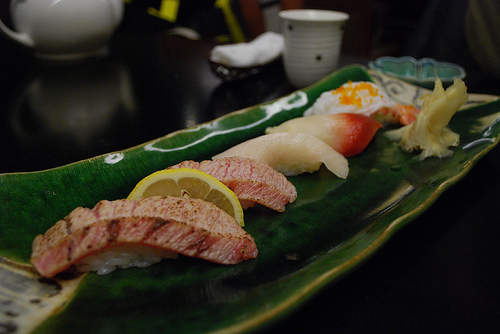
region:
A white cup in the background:
[280, 3, 350, 73]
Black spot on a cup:
[314, 52, 322, 60]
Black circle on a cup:
[315, 53, 323, 62]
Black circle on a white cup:
[315, 53, 323, 60]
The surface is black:
[29, 65, 155, 122]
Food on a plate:
[16, 46, 445, 303]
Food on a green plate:
[21, 75, 458, 307]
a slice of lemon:
[109, 163, 257, 228]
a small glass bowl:
[356, 45, 473, 110]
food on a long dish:
[3, 50, 498, 332]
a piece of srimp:
[7, 187, 304, 284]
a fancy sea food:
[15, 80, 435, 332]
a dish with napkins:
[198, 21, 283, 84]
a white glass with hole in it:
[236, 9, 366, 93]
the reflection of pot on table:
[8, 27, 149, 159]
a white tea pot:
[2, 1, 180, 71]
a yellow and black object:
[146, 2, 251, 37]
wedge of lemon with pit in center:
[125, 166, 243, 229]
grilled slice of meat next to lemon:
[32, 194, 259, 274]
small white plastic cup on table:
[277, 7, 347, 89]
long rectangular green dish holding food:
[3, 63, 498, 333]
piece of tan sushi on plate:
[215, 128, 348, 183]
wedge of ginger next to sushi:
[384, 75, 467, 159]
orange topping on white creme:
[329, 75, 381, 111]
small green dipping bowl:
[370, 53, 465, 88]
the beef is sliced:
[101, 186, 200, 258]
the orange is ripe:
[166, 166, 207, 198]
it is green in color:
[303, 177, 394, 234]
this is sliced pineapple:
[265, 109, 363, 172]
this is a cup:
[283, 1, 338, 73]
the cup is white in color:
[286, 8, 346, 68]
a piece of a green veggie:
[271, 151, 387, 275]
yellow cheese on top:
[326, 75, 383, 110]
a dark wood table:
[58, 28, 198, 132]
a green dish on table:
[3, 43, 497, 315]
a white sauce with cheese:
[298, 68, 397, 117]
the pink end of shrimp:
[336, 94, 381, 155]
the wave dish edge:
[313, 175, 469, 321]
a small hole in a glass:
[305, 45, 328, 67]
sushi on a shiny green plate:
[1, 61, 498, 332]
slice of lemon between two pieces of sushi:
[30, 150, 299, 279]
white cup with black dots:
[277, 6, 347, 88]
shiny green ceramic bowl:
[368, 54, 466, 88]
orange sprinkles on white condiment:
[304, 73, 396, 120]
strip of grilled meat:
[32, 196, 258, 276]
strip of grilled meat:
[168, 159, 297, 210]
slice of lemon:
[127, 168, 244, 228]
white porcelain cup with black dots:
[277, 10, 347, 86]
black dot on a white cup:
[314, 53, 324, 64]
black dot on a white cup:
[286, 24, 293, 31]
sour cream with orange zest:
[302, 81, 397, 115]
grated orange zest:
[332, 81, 379, 107]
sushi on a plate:
[37, 174, 244, 294]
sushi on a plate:
[180, 158, 270, 217]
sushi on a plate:
[272, 97, 376, 163]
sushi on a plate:
[318, 83, 411, 131]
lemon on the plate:
[127, 155, 257, 236]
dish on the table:
[365, 30, 452, 123]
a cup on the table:
[272, 6, 361, 96]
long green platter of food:
[1, 63, 497, 333]